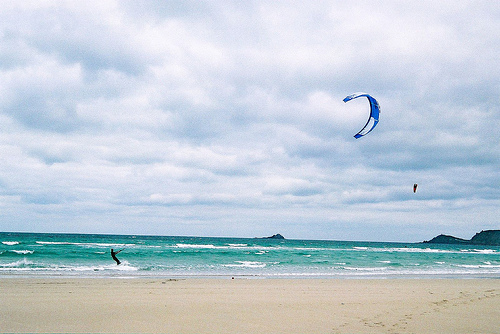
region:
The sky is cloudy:
[5, 0, 495, 220]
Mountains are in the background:
[420, 220, 495, 245]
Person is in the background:
[100, 240, 130, 270]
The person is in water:
[105, 230, 140, 275]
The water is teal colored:
[5, 230, 495, 265]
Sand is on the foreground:
[5, 270, 495, 330]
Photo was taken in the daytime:
[0, 0, 495, 320]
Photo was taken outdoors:
[5, 81, 495, 326]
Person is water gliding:
[95, 70, 400, 270]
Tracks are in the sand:
[408, 285, 499, 323]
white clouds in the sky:
[56, 50, 216, 157]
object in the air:
[315, 86, 387, 153]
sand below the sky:
[231, 292, 293, 325]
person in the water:
[68, 223, 150, 298]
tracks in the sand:
[387, 270, 474, 329]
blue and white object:
[296, 86, 391, 168]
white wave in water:
[175, 223, 229, 272]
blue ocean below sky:
[166, 231, 226, 273]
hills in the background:
[406, 213, 493, 271]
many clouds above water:
[108, 38, 269, 125]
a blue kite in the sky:
[338, 86, 388, 151]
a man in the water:
[108, 244, 127, 266]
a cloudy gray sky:
[1, 0, 499, 246]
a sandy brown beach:
[1, 273, 496, 332]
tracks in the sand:
[328, 285, 498, 331]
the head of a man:
[108, 244, 118, 253]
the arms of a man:
[110, 246, 125, 257]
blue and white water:
[1, 227, 498, 275]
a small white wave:
[171, 237, 221, 254]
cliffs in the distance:
[418, 225, 497, 250]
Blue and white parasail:
[327, 75, 404, 160]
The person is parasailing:
[73, 74, 395, 274]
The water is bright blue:
[47, 225, 350, 274]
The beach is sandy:
[6, 248, 485, 330]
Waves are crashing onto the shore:
[198, 228, 420, 270]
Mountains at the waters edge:
[401, 212, 496, 254]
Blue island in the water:
[248, 211, 298, 248]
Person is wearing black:
[94, 231, 161, 279]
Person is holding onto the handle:
[84, 227, 175, 283]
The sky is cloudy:
[39, 26, 286, 219]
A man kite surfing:
[108, 243, 127, 268]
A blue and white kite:
[336, 91, 381, 148]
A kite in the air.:
[339, 84, 384, 151]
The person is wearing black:
[105, 244, 131, 269]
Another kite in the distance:
[407, 179, 427, 194]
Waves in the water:
[167, 237, 436, 258]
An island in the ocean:
[255, 222, 300, 248]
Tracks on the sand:
[390, 289, 495, 333]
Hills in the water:
[418, 221, 498, 253]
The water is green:
[192, 246, 353, 273]